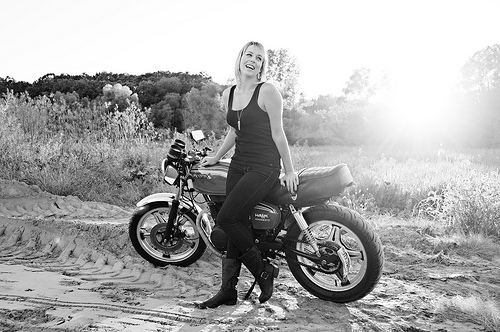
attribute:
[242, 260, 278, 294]
boots — dark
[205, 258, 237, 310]
boots — dark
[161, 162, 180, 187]
mirror — rear-view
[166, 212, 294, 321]
boots — black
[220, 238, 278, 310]
boot — black, leather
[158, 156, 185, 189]
mirror — side-view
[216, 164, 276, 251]
pants — long 